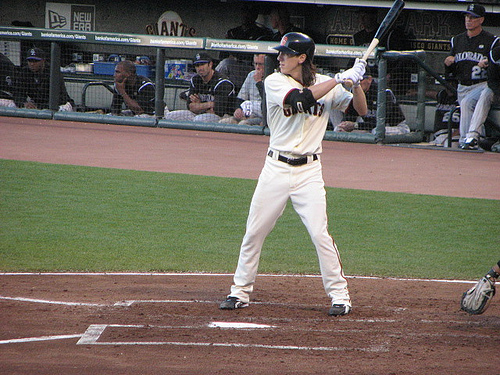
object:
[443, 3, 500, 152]
players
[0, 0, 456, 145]
dugout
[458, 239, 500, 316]
catcher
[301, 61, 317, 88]
hair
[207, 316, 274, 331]
home plate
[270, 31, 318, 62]
helmet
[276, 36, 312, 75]
head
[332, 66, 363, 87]
gloves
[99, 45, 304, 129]
team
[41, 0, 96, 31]
sign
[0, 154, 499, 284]
turf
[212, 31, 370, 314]
batter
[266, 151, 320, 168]
belt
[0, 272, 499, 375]
dirt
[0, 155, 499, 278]
grass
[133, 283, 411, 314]
lines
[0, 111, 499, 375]
field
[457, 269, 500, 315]
glove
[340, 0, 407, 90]
bat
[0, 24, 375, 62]
metal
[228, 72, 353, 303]
uniform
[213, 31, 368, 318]
man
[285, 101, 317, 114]
elbow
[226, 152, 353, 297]
trouser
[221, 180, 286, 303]
leg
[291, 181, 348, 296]
leg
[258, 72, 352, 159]
jersey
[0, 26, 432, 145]
fence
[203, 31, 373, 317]
game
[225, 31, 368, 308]
player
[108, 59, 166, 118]
people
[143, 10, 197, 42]
giants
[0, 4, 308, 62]
wall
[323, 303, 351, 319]
cleat